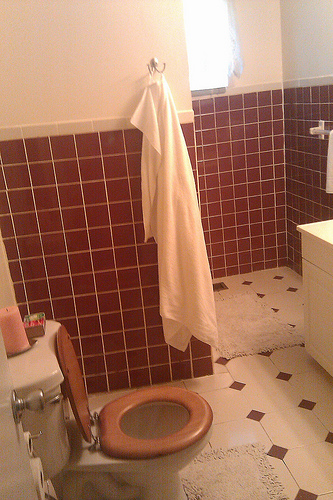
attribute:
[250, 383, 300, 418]
tile floor — square, white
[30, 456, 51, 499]
toilet paper — white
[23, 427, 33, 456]
toilet paper — white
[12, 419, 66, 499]
toilet paper — white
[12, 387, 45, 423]
doorknob — silver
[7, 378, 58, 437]
doorknob — silver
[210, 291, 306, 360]
rug — white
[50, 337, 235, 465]
toilet — wooden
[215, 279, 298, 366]
rug — white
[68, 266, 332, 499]
tile floor — white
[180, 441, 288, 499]
mat — white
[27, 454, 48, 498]
toilet tissue — roll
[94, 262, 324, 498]
tiles — white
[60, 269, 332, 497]
pattern — diamond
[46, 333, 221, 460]
seat — wooden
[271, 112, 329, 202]
towel — white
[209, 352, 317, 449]
floor — white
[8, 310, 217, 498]
toilet — white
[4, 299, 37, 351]
candle — pink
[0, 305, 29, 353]
candle — pink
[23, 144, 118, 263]
tile — brown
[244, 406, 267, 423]
brown tile — diamond-shaped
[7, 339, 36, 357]
candle holder — flat, silver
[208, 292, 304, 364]
rug — white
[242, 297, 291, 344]
mat — white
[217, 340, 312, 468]
tiles — brown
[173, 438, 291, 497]
rug — white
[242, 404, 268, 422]
diamond — brown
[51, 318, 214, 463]
seat — brown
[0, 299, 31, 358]
candle — pink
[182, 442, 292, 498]
rug — white